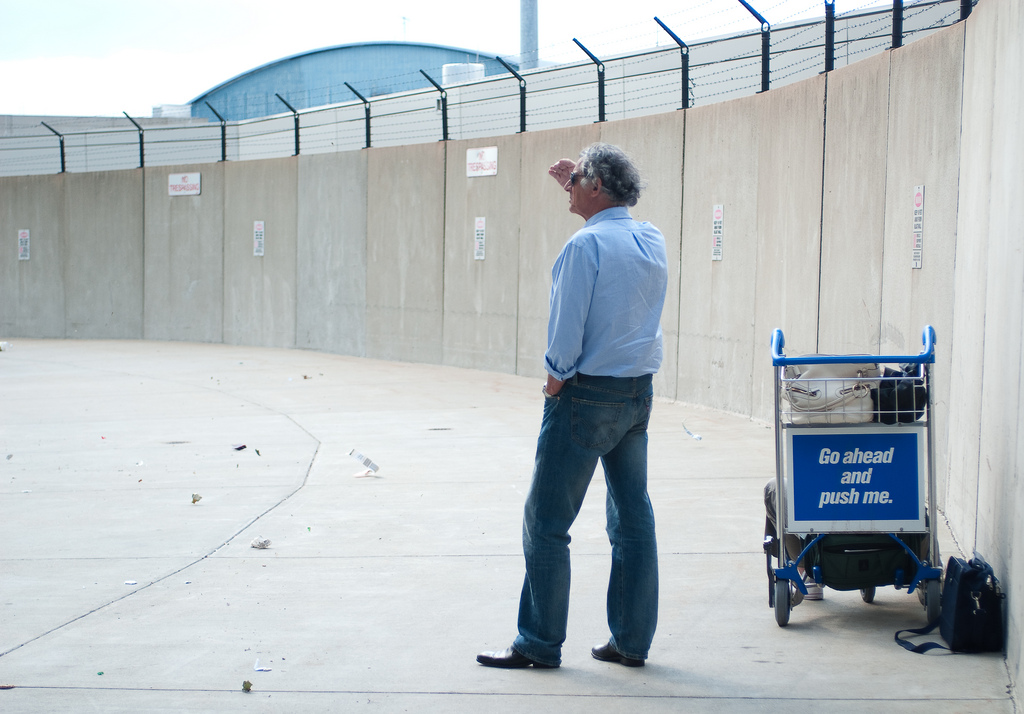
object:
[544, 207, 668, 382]
shirt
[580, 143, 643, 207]
hair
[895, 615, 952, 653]
strap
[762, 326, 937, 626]
luggage cart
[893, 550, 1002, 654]
bag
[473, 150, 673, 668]
man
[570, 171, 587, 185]
sunglasses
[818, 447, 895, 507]
letter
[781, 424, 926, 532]
sign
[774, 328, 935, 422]
cart